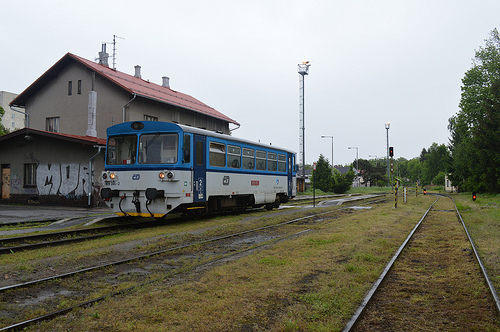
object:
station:
[0, 47, 332, 226]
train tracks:
[0, 220, 146, 242]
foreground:
[0, 196, 500, 331]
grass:
[223, 239, 338, 308]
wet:
[355, 290, 373, 308]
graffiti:
[34, 163, 95, 207]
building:
[0, 43, 240, 207]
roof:
[8, 50, 245, 126]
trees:
[374, 23, 500, 193]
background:
[291, 51, 500, 210]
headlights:
[101, 170, 175, 182]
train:
[100, 120, 306, 219]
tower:
[293, 61, 312, 196]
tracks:
[80, 227, 381, 321]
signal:
[471, 189, 480, 200]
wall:
[0, 141, 101, 205]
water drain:
[86, 154, 97, 207]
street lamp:
[382, 119, 394, 132]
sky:
[0, 1, 500, 168]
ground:
[0, 158, 500, 331]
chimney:
[86, 85, 96, 138]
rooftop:
[66, 51, 243, 127]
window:
[139, 131, 182, 164]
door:
[193, 135, 206, 205]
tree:
[442, 24, 500, 194]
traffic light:
[386, 148, 392, 162]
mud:
[76, 243, 156, 287]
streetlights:
[320, 119, 394, 180]